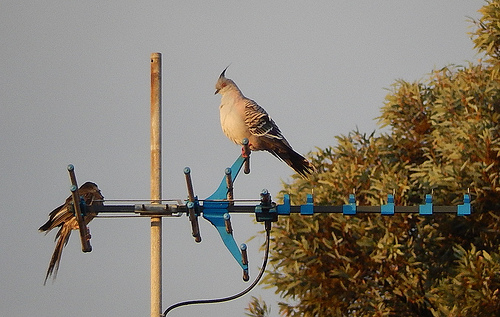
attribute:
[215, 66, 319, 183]
bird — sitting, standing, big, brown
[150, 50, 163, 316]
pole — brown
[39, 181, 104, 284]
bird — standing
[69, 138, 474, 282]
antenna — blue, colored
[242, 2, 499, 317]
tree — green, colored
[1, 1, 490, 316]
sky — dark, gray, blue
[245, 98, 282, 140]
wing — colored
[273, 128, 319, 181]
tail — long, black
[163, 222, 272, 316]
cable — black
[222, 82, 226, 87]
eye — red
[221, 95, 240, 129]
chest — white